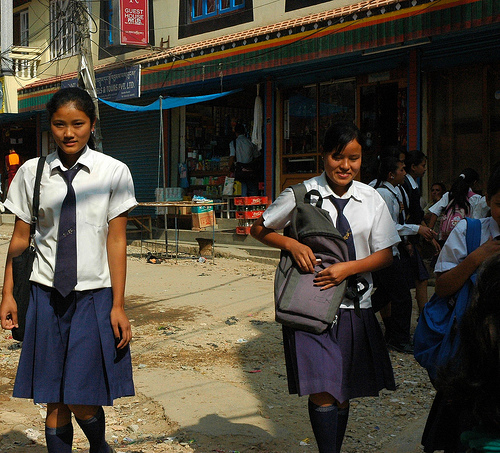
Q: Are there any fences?
A: No, there are no fences.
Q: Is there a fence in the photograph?
A: No, there are no fences.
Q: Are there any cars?
A: No, there are no cars.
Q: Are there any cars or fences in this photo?
A: No, there are no cars or fences.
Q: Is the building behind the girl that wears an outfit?
A: Yes, the building is behind the girl.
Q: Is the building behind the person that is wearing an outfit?
A: Yes, the building is behind the girl.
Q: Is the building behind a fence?
A: No, the building is behind the girl.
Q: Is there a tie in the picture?
A: Yes, there is a tie.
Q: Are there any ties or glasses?
A: Yes, there is a tie.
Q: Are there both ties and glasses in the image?
A: No, there is a tie but no glasses.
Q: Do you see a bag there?
A: Yes, there is a bag.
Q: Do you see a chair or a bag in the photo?
A: Yes, there is a bag.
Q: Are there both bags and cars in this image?
A: No, there is a bag but no cars.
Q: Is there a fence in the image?
A: No, there are no fences.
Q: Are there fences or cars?
A: No, there are no fences or cars.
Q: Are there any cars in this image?
A: No, there are no cars.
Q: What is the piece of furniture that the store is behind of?
A: The piece of furniture is a table.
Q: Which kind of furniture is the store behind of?
A: The store is behind the table.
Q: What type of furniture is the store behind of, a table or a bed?
A: The store is behind a table.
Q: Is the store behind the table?
A: Yes, the store is behind the table.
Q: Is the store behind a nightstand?
A: No, the store is behind the table.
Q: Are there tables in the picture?
A: Yes, there is a table.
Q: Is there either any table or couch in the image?
A: Yes, there is a table.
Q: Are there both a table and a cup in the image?
A: No, there is a table but no cups.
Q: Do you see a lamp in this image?
A: No, there are no lamps.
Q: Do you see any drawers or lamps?
A: No, there are no lamps or drawers.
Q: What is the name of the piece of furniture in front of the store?
A: The piece of furniture is a table.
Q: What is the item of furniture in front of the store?
A: The piece of furniture is a table.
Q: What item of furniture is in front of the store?
A: The piece of furniture is a table.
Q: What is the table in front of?
A: The table is in front of the store.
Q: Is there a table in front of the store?
A: Yes, there is a table in front of the store.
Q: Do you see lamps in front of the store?
A: No, there is a table in front of the store.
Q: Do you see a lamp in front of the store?
A: No, there is a table in front of the store.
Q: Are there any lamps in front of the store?
A: No, there is a table in front of the store.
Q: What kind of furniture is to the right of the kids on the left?
A: The piece of furniture is a table.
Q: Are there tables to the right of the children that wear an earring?
A: Yes, there is a table to the right of the children.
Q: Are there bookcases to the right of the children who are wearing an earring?
A: No, there is a table to the right of the kids.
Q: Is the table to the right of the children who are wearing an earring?
A: Yes, the table is to the right of the children.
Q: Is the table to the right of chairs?
A: No, the table is to the right of the children.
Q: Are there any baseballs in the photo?
A: No, there are no baseballs.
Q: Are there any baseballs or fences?
A: No, there are no baseballs or fences.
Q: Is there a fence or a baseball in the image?
A: No, there are no baseballs or fences.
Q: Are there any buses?
A: No, there are no buses.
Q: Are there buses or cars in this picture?
A: No, there are no buses or cars.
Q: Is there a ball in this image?
A: No, there are no balls.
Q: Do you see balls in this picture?
A: No, there are no balls.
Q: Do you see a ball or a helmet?
A: No, there are no balls or helmets.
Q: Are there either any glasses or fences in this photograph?
A: No, there are no glasses or fences.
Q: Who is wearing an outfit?
A: The girl is wearing an outfit.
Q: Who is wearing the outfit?
A: The girl is wearing an outfit.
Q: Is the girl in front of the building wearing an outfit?
A: Yes, the girl is wearing an outfit.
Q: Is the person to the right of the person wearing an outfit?
A: Yes, the girl is wearing an outfit.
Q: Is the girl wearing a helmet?
A: No, the girl is wearing an outfit.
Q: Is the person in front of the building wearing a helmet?
A: No, the girl is wearing an outfit.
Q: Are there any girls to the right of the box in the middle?
A: Yes, there is a girl to the right of the box.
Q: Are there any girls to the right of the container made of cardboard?
A: Yes, there is a girl to the right of the box.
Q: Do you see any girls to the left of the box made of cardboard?
A: No, the girl is to the right of the box.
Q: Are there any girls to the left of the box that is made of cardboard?
A: No, the girl is to the right of the box.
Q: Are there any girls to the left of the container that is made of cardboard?
A: No, the girl is to the right of the box.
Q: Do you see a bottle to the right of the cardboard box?
A: No, there is a girl to the right of the box.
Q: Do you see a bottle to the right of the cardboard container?
A: No, there is a girl to the right of the box.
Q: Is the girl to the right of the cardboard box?
A: Yes, the girl is to the right of the box.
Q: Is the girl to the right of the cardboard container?
A: Yes, the girl is to the right of the box.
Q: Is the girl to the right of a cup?
A: No, the girl is to the right of the box.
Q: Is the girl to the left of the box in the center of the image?
A: No, the girl is to the right of the box.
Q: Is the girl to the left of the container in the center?
A: No, the girl is to the right of the box.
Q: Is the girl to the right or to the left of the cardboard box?
A: The girl is to the right of the box.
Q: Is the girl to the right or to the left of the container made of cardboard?
A: The girl is to the right of the box.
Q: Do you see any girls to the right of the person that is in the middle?
A: Yes, there is a girl to the right of the person.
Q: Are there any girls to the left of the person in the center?
A: No, the girl is to the right of the person.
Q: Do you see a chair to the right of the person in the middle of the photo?
A: No, there is a girl to the right of the person.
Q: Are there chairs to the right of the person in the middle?
A: No, there is a girl to the right of the person.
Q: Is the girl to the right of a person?
A: Yes, the girl is to the right of a person.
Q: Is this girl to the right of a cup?
A: No, the girl is to the right of a person.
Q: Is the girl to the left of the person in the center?
A: No, the girl is to the right of the person.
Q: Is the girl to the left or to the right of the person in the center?
A: The girl is to the right of the person.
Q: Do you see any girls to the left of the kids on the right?
A: Yes, there is a girl to the left of the children.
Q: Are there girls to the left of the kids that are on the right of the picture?
A: Yes, there is a girl to the left of the children.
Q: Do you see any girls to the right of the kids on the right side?
A: No, the girl is to the left of the kids.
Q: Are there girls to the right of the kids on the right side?
A: No, the girl is to the left of the kids.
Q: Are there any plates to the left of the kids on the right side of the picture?
A: No, there is a girl to the left of the kids.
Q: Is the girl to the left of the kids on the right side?
A: Yes, the girl is to the left of the kids.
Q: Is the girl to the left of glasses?
A: No, the girl is to the left of the kids.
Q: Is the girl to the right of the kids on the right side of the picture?
A: No, the girl is to the left of the children.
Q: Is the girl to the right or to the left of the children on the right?
A: The girl is to the left of the children.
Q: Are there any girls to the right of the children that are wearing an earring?
A: Yes, there is a girl to the right of the children.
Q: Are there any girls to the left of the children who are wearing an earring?
A: No, the girl is to the right of the children.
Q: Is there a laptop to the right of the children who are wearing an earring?
A: No, there is a girl to the right of the children.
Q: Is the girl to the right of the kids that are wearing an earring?
A: Yes, the girl is to the right of the kids.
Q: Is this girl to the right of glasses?
A: No, the girl is to the right of the kids.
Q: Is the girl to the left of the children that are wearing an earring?
A: No, the girl is to the right of the kids.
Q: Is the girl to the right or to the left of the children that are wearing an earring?
A: The girl is to the right of the children.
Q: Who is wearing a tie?
A: The girl is wearing a tie.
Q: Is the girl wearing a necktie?
A: Yes, the girl is wearing a necktie.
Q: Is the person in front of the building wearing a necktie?
A: Yes, the girl is wearing a necktie.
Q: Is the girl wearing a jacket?
A: No, the girl is wearing a necktie.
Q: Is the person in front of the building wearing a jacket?
A: No, the girl is wearing a necktie.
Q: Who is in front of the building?
A: The girl is in front of the building.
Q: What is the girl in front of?
A: The girl is in front of the building.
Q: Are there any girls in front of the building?
A: Yes, there is a girl in front of the building.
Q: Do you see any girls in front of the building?
A: Yes, there is a girl in front of the building.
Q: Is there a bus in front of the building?
A: No, there is a girl in front of the building.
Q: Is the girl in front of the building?
A: Yes, the girl is in front of the building.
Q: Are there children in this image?
A: Yes, there are children.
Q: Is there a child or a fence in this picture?
A: Yes, there are children.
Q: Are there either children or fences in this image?
A: Yes, there are children.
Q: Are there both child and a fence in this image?
A: No, there are children but no fences.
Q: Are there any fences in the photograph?
A: No, there are no fences.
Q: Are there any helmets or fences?
A: No, there are no fences or helmets.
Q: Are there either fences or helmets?
A: No, there are no fences or helmets.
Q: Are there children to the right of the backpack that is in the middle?
A: Yes, there are children to the right of the backpack.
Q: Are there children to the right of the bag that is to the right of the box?
A: Yes, there are children to the right of the backpack.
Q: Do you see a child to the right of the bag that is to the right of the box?
A: Yes, there are children to the right of the backpack.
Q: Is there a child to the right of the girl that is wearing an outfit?
A: Yes, there are children to the right of the girl.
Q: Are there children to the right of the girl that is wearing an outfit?
A: Yes, there are children to the right of the girl.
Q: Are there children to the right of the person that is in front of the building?
A: Yes, there are children to the right of the girl.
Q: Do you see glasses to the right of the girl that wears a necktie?
A: No, there are children to the right of the girl.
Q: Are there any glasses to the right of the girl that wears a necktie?
A: No, there are children to the right of the girl.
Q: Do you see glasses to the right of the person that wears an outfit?
A: No, there are children to the right of the girl.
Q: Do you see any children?
A: Yes, there are children.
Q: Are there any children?
A: Yes, there are children.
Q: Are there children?
A: Yes, there are children.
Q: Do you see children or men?
A: Yes, there are children.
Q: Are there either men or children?
A: Yes, there are children.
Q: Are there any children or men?
A: Yes, there are children.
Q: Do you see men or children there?
A: Yes, there are children.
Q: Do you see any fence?
A: No, there are no fences.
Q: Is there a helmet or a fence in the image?
A: No, there are no fences or helmets.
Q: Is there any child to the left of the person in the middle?
A: Yes, there are children to the left of the person.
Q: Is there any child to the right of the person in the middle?
A: No, the children are to the left of the person.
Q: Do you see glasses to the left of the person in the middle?
A: No, there are children to the left of the person.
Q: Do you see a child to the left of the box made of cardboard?
A: Yes, there are children to the left of the box.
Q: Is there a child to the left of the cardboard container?
A: Yes, there are children to the left of the box.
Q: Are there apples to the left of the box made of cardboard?
A: No, there are children to the left of the box.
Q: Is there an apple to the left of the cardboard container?
A: No, there are children to the left of the box.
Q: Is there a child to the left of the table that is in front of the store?
A: Yes, there are children to the left of the table.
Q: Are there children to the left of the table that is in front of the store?
A: Yes, there are children to the left of the table.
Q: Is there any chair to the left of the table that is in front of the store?
A: No, there are children to the left of the table.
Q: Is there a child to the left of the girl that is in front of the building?
A: Yes, there are children to the left of the girl.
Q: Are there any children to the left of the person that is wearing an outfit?
A: Yes, there are children to the left of the girl.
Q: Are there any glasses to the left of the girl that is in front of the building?
A: No, there are children to the left of the girl.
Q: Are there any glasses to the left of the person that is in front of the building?
A: No, there are children to the left of the girl.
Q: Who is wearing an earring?
A: The kids are wearing an earring.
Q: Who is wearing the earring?
A: The kids are wearing an earring.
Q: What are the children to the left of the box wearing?
A: The kids are wearing an earring.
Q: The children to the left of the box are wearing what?
A: The kids are wearing an earring.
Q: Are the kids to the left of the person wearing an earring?
A: Yes, the kids are wearing an earring.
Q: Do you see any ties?
A: Yes, there is a tie.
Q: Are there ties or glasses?
A: Yes, there is a tie.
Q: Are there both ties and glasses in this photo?
A: No, there is a tie but no glasses.